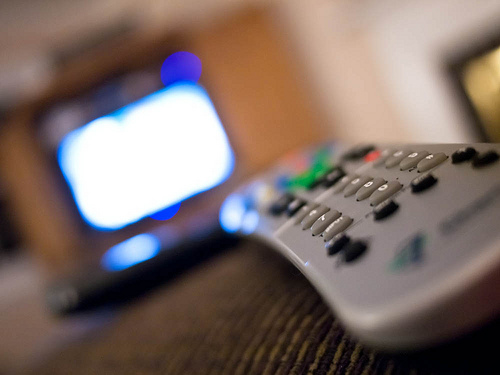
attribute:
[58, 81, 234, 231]
screen — on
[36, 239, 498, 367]
couch — soft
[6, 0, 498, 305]
wall — blurred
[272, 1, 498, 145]
wall — blurred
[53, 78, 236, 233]
television screen — blurry, out of focus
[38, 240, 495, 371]
pillow — brown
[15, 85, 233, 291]
entertainment system — light brown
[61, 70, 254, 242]
tv — on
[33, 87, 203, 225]
screen — blurry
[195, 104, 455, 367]
remote — gray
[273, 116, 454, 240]
buttons — gray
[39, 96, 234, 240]
tv — far away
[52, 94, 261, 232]
light — blue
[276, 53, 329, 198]
buttons — green